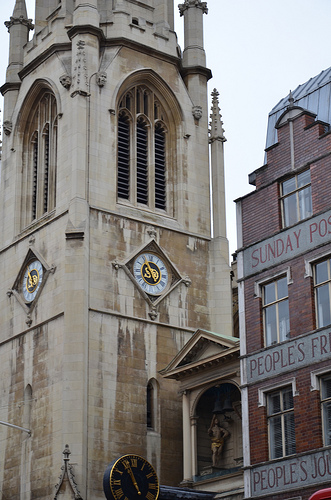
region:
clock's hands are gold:
[136, 252, 182, 308]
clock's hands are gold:
[134, 242, 166, 293]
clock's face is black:
[95, 444, 165, 498]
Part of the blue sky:
[229, 25, 258, 55]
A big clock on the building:
[127, 246, 175, 298]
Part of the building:
[49, 342, 60, 387]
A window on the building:
[254, 268, 297, 350]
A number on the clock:
[140, 461, 147, 470]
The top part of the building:
[285, 86, 295, 106]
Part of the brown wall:
[123, 370, 135, 399]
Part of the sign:
[261, 462, 298, 485]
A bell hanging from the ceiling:
[221, 395, 236, 413]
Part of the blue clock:
[125, 480, 130, 489]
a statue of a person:
[199, 412, 236, 472]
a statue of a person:
[196, 398, 222, 480]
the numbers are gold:
[103, 456, 150, 498]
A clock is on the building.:
[133, 250, 169, 295]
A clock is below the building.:
[103, 455, 159, 499]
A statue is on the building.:
[207, 411, 229, 467]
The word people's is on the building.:
[247, 340, 306, 381]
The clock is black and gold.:
[103, 453, 159, 499]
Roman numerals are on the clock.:
[111, 477, 124, 498]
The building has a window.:
[117, 84, 170, 207]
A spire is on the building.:
[208, 88, 226, 247]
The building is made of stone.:
[92, 327, 135, 441]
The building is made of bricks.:
[245, 196, 274, 233]